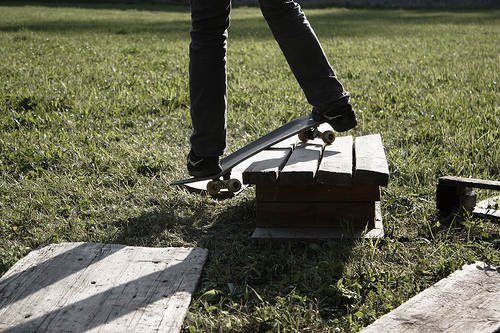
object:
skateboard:
[177, 105, 339, 196]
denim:
[187, 3, 350, 154]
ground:
[384, 158, 398, 188]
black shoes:
[186, 152, 223, 178]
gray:
[12, 265, 40, 315]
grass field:
[0, 0, 499, 331]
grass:
[340, 12, 496, 79]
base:
[224, 127, 391, 239]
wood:
[355, 129, 392, 192]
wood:
[319, 135, 355, 187]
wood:
[280, 133, 317, 188]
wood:
[246, 122, 282, 186]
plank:
[243, 132, 390, 230]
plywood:
[1, 240, 211, 331]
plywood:
[354, 260, 500, 332]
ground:
[35, 222, 366, 328]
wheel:
[298, 128, 308, 141]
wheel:
[321, 131, 331, 145]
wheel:
[226, 178, 240, 193]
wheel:
[207, 178, 219, 194]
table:
[236, 125, 394, 243]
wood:
[439, 173, 500, 223]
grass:
[336, 21, 376, 54]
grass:
[31, 133, 71, 168]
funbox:
[244, 124, 403, 250]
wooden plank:
[0, 233, 210, 331]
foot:
[313, 94, 357, 132]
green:
[63, 135, 170, 180]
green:
[100, 25, 195, 108]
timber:
[242, 133, 389, 241]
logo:
[187, 155, 202, 170]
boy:
[186, 0, 359, 178]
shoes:
[316, 100, 360, 133]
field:
[59, 35, 194, 175]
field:
[387, 17, 477, 114]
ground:
[37, 57, 417, 318]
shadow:
[0, 177, 345, 332]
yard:
[1, 1, 500, 332]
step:
[214, 129, 465, 198]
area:
[2, 4, 500, 333]